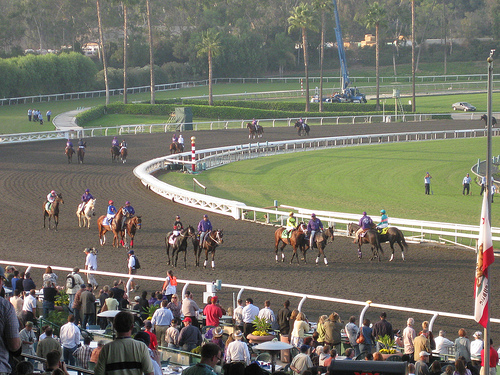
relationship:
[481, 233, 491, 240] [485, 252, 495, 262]
white and red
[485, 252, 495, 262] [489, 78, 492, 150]
red and white pole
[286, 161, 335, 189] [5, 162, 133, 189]
grassy section in track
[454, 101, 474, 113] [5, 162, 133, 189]
car near track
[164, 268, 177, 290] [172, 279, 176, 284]
woman wearing orange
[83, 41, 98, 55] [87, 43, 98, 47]
house with roof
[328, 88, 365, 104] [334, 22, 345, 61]
truck with ladder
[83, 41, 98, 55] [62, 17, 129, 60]
building in background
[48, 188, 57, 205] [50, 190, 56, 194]
jockey with pink helmet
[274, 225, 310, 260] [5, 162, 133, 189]
horse on track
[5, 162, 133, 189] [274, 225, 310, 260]
track with horse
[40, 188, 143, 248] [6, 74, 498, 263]
horses running outside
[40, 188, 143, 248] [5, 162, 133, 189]
horses running on track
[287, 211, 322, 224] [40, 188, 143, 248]
people riding horses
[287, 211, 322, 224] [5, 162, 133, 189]
people on a track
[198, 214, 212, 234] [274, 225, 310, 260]
person riding a horse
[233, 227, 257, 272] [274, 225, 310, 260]
race track with horse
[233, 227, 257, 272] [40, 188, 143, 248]
race track with horses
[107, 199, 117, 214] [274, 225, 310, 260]
person riding a horse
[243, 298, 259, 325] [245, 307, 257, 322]
man wearing white shirt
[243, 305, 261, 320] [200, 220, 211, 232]
man wearing purple shirt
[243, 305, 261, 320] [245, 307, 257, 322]
man wearing shirt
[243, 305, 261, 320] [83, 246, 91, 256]
man wearing hat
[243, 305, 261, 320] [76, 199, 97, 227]
man riding white horse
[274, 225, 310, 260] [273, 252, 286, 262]
horse has bandanges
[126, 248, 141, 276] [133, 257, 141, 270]
man wearing backpack